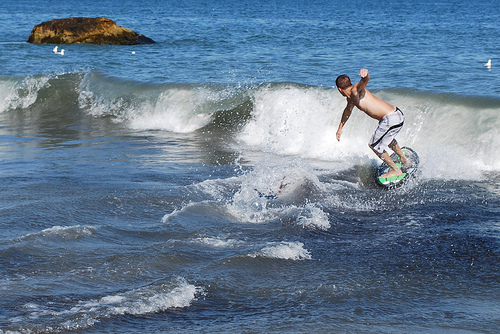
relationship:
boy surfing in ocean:
[334, 67, 409, 180] [5, 6, 497, 318]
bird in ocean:
[481, 55, 496, 69] [5, 6, 497, 318]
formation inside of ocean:
[24, 14, 156, 49] [5, 6, 497, 318]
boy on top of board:
[334, 67, 409, 180] [374, 147, 419, 188]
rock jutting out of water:
[30, 11, 140, 51] [52, 41, 297, 233]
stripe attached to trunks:
[366, 117, 411, 152] [373, 112, 403, 155]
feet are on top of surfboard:
[374, 156, 411, 179] [373, 142, 423, 187]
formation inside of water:
[24, 14, 156, 49] [30, 46, 177, 85]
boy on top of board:
[334, 67, 409, 180] [374, 142, 420, 188]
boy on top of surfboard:
[334, 67, 409, 180] [373, 142, 423, 187]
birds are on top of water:
[30, 40, 499, 76] [150, 47, 306, 78]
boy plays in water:
[322, 65, 419, 185] [2, 0, 495, 330]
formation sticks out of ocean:
[32, 14, 158, 54] [0, 3, 498, 333]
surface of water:
[232, 275, 499, 324] [1, 40, 497, 327]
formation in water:
[24, 14, 156, 49] [1, 40, 497, 327]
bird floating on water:
[483, 59, 496, 70] [1, 40, 497, 327]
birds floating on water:
[50, 43, 66, 57] [1, 40, 497, 327]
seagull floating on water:
[125, 46, 140, 61] [1, 40, 497, 327]